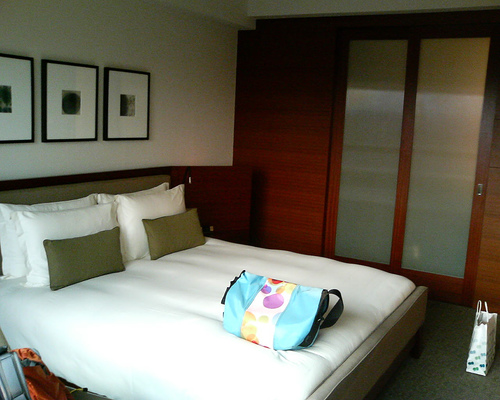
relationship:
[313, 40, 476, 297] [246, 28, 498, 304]
door attached to closet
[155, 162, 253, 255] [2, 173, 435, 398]
cabinet next to bed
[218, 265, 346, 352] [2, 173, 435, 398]
bag resting on bed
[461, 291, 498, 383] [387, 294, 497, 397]
bag resting on floor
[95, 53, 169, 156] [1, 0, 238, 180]
picture hanging on wall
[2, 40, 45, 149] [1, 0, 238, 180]
picture hanging on wall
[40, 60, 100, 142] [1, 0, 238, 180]
photos hanging on wall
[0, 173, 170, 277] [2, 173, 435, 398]
headboard attached to bed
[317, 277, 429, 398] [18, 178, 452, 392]
footboard attached to bed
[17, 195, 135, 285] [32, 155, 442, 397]
pillow on bed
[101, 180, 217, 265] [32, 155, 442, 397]
pillow on bed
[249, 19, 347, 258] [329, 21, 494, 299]
wall next to door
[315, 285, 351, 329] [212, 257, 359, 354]
handles attached to bag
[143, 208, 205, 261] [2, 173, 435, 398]
pillow on bed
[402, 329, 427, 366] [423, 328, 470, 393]
foot on ground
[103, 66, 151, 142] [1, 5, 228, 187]
picture on wall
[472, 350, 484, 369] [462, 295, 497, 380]
blue rectangles on bag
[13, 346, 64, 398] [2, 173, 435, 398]
orange backpack beside bed